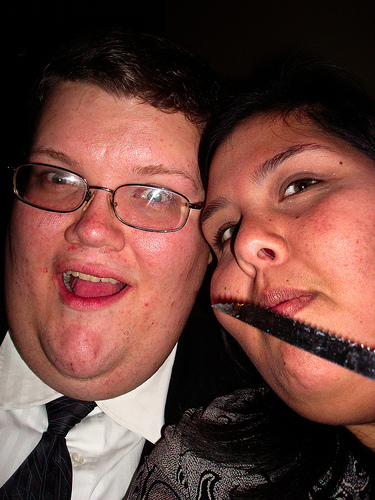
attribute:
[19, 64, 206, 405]
man — posing, smiling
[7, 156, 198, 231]
glasses — thin, wire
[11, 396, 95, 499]
tie — black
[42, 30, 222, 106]
hair — brown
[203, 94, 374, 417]
woman — posing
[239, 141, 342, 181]
eyebrow — bushy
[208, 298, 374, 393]
knife blade — black, serrated, dirty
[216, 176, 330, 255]
eyes — brown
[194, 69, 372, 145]
hair — black, long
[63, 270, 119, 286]
teeth — brown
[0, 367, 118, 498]
shirt — white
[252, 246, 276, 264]
nostril — big